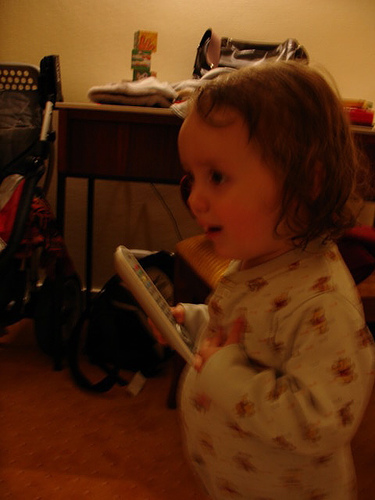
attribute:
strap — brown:
[193, 30, 212, 83]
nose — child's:
[188, 187, 209, 211]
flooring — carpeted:
[0, 315, 215, 498]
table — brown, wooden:
[28, 63, 357, 240]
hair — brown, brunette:
[191, 60, 360, 250]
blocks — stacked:
[128, 28, 160, 83]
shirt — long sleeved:
[159, 239, 369, 365]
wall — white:
[255, 13, 333, 39]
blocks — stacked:
[118, 13, 171, 76]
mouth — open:
[196, 214, 226, 237]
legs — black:
[84, 182, 95, 293]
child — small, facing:
[136, 56, 373, 498]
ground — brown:
[63, 427, 113, 472]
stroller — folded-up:
[0, 48, 85, 357]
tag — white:
[123, 367, 148, 399]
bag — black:
[81, 246, 178, 384]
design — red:
[308, 276, 331, 298]